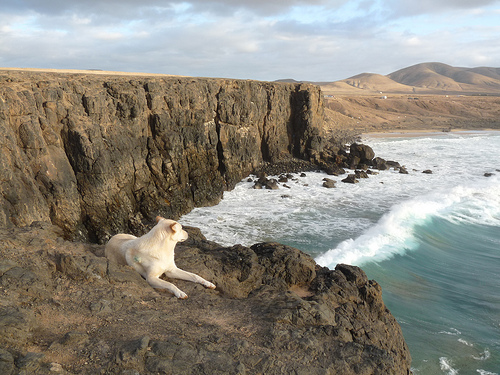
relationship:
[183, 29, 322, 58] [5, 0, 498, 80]
clouds in sky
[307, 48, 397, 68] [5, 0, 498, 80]
clouds in sky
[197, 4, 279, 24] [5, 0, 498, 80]
clouds in sky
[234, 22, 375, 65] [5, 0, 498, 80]
clouds in sky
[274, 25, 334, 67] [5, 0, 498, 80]
clouds in sky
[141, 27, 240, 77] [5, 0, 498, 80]
clouds in sky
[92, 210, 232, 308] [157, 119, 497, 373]
dog looking at ocean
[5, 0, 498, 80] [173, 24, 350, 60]
sky with clouds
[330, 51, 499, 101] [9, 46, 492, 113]
hills in background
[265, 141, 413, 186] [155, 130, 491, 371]
rocks in water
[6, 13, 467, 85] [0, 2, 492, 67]
clouds in sky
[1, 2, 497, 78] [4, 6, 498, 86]
clouds in sky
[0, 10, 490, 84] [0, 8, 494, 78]
clouds in sky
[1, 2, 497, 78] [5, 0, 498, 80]
clouds in sky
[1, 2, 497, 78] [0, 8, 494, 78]
clouds in sky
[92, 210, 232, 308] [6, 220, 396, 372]
dog sits on rocks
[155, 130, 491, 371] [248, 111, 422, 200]
water meets rocks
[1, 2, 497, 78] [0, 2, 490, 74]
clouds in sky